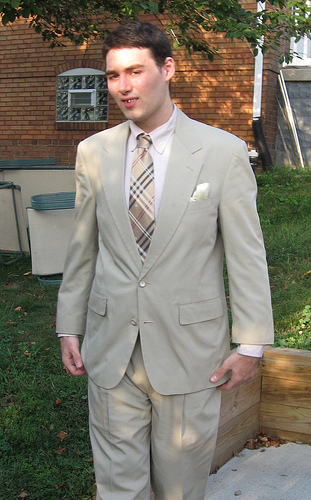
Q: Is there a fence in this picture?
A: No, there are no fences.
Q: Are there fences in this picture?
A: No, there are no fences.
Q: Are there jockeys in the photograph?
A: No, there are no jockeys.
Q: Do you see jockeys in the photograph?
A: No, there are no jockeys.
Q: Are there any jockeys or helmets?
A: No, there are no jockeys or helmets.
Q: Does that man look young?
A: Yes, the man is young.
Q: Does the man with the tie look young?
A: Yes, the man is young.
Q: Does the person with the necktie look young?
A: Yes, the man is young.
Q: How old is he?
A: The man is young.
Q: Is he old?
A: No, the man is young.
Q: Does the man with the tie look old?
A: No, the man is young.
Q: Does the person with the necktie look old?
A: No, the man is young.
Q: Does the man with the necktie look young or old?
A: The man is young.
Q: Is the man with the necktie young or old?
A: The man is young.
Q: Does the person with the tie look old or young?
A: The man is young.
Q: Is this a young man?
A: Yes, this is a young man.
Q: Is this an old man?
A: No, this is a young man.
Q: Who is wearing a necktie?
A: The man is wearing a necktie.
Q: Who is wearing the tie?
A: The man is wearing a necktie.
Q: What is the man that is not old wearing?
A: The man is wearing a necktie.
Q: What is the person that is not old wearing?
A: The man is wearing a necktie.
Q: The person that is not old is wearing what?
A: The man is wearing a necktie.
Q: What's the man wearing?
A: The man is wearing a necktie.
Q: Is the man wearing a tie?
A: Yes, the man is wearing a tie.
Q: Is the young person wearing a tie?
A: Yes, the man is wearing a tie.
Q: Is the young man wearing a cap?
A: No, the man is wearing a tie.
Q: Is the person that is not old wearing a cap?
A: No, the man is wearing a tie.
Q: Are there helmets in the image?
A: No, there are no helmets.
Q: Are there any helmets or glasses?
A: No, there are no helmets or glasses.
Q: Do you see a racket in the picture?
A: No, there are no rackets.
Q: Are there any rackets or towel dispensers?
A: No, there are no rackets or towel dispensers.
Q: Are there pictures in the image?
A: No, there are no pictures.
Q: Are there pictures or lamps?
A: No, there are no pictures or lamps.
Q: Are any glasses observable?
A: No, there are no glasses.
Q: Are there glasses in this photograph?
A: No, there are no glasses.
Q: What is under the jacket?
A: The dress shirt is under the jacket.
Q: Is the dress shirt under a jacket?
A: Yes, the dress shirt is under a jacket.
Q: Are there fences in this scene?
A: No, there are no fences.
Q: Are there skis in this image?
A: No, there are no skis.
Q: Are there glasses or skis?
A: No, there are no skis or glasses.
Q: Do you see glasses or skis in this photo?
A: No, there are no skis or glasses.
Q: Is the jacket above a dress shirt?
A: Yes, the jacket is above a dress shirt.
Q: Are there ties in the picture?
A: Yes, there is a tie.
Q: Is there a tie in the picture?
A: Yes, there is a tie.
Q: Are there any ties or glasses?
A: Yes, there is a tie.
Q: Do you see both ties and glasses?
A: No, there is a tie but no glasses.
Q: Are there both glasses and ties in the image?
A: No, there is a tie but no glasses.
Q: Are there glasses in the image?
A: No, there are no glasses.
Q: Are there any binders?
A: No, there are no binders.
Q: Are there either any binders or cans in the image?
A: No, there are no binders or cans.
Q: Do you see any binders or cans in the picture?
A: No, there are no binders or cans.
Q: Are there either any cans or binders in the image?
A: No, there are no binders or cans.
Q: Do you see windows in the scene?
A: Yes, there is a window.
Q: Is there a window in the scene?
A: Yes, there is a window.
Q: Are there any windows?
A: Yes, there is a window.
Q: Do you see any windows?
A: Yes, there is a window.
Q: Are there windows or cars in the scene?
A: Yes, there is a window.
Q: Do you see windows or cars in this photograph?
A: Yes, there is a window.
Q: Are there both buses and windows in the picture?
A: No, there is a window but no buses.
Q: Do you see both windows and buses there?
A: No, there is a window but no buses.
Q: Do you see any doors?
A: No, there are no doors.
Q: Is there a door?
A: No, there are no doors.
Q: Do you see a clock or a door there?
A: No, there are no doors or clocks.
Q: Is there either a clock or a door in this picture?
A: No, there are no doors or clocks.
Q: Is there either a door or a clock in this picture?
A: No, there are no doors or clocks.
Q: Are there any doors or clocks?
A: No, there are no doors or clocks.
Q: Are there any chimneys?
A: No, there are no chimneys.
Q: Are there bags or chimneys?
A: No, there are no chimneys or bags.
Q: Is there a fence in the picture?
A: No, there are no fences.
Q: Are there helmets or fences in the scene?
A: No, there are no fences or helmets.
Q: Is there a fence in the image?
A: No, there are no fences.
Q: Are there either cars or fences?
A: No, there are no fences or cars.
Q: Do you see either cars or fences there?
A: No, there are no fences or cars.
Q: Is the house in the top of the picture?
A: Yes, the house is in the top of the image.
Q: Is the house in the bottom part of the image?
A: No, the house is in the top of the image.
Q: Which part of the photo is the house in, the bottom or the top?
A: The house is in the top of the image.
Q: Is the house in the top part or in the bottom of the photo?
A: The house is in the top of the image.